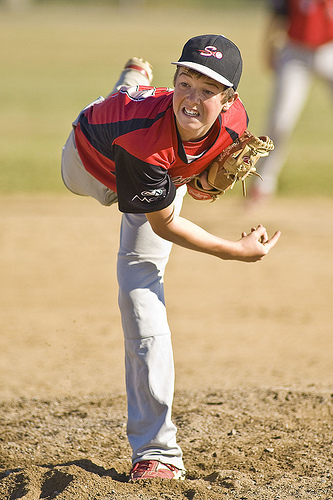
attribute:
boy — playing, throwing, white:
[62, 34, 286, 482]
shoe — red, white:
[126, 457, 187, 486]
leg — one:
[116, 202, 189, 483]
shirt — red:
[70, 86, 250, 211]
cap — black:
[170, 34, 242, 94]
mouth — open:
[177, 106, 206, 121]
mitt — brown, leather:
[187, 135, 274, 203]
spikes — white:
[123, 56, 155, 75]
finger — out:
[261, 230, 286, 253]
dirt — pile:
[1, 438, 331, 498]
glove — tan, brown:
[186, 135, 273, 204]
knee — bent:
[116, 271, 174, 323]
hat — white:
[172, 36, 242, 90]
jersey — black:
[74, 83, 251, 214]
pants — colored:
[60, 87, 187, 471]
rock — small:
[228, 427, 238, 437]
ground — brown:
[0, 195, 331, 498]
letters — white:
[129, 187, 162, 205]